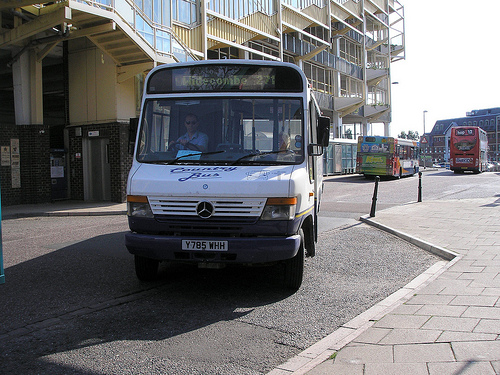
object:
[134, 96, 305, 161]
windshield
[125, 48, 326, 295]
bus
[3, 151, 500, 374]
street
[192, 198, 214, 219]
sign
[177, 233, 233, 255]
plate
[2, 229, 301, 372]
shadow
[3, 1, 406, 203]
building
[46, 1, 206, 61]
stair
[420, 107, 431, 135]
post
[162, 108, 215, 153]
driver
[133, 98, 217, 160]
side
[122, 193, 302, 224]
headlight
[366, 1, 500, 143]
sky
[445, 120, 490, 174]
bus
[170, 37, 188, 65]
windows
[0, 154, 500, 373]
road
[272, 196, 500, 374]
sidewalk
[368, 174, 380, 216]
posts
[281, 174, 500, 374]
curb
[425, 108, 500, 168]
building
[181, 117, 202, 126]
sunglasses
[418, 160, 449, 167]
curb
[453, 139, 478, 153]
advertisement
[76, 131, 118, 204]
entrance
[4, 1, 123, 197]
building